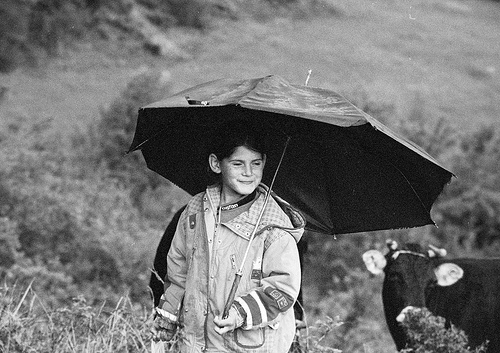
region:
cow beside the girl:
[357, 237, 495, 350]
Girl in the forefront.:
[145, 123, 310, 351]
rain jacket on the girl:
[154, 128, 304, 349]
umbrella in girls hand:
[120, 49, 459, 329]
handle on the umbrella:
[212, 273, 256, 336]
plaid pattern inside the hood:
[234, 196, 298, 236]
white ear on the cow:
[359, 243, 395, 285]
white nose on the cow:
[390, 301, 431, 331]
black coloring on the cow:
[358, 235, 498, 351]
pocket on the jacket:
[230, 323, 272, 352]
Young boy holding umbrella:
[122, 59, 454, 343]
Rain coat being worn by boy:
[147, 175, 305, 347]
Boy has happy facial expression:
[219, 137, 259, 194]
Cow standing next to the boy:
[349, 231, 491, 351]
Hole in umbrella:
[177, 92, 213, 113]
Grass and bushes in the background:
[12, 8, 494, 348]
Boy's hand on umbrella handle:
[206, 268, 255, 336]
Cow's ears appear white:
[352, 232, 474, 283]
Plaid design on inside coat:
[226, 200, 283, 237]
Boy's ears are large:
[203, 140, 226, 182]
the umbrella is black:
[165, 74, 440, 237]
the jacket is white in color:
[173, 210, 291, 352]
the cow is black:
[383, 240, 498, 338]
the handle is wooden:
[216, 274, 249, 316]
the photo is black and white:
[3, 2, 499, 349]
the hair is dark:
[221, 122, 271, 155]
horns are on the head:
[391, 237, 448, 264]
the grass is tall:
[7, 282, 139, 351]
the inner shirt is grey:
[223, 207, 245, 222]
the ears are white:
[440, 262, 467, 284]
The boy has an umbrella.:
[127, 56, 457, 351]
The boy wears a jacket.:
[120, 55, 455, 351]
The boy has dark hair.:
[119, 58, 456, 351]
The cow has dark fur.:
[358, 234, 498, 351]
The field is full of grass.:
[0, 0, 499, 351]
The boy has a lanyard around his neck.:
[155, 126, 306, 351]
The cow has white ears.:
[358, 234, 498, 351]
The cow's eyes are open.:
[358, 235, 498, 351]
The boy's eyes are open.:
[151, 136, 308, 351]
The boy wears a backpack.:
[147, 125, 307, 350]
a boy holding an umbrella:
[107, 56, 465, 351]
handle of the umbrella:
[201, 264, 268, 337]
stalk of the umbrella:
[238, 170, 268, 263]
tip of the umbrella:
[302, 70, 317, 80]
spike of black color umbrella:
[292, 65, 322, 80]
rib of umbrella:
[297, 82, 362, 118]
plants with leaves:
[12, 141, 112, 322]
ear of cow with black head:
[362, 247, 470, 333]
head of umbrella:
[371, 232, 461, 338]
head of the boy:
[208, 137, 269, 192]